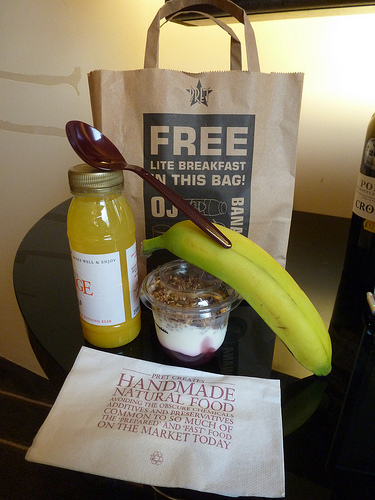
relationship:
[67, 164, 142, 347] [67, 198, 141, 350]
bottle of orange juice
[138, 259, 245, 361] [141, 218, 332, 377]
parfait under banana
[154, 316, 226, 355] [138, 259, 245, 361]
yogurt in parfait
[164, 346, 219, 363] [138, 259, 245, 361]
fruit in parfait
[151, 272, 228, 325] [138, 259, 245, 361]
granola on parfait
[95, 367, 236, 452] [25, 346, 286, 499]
print on napkin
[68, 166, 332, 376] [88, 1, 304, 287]
breakfast next to bag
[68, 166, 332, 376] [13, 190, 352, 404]
breakfast on table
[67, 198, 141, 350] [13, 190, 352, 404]
orange juice on table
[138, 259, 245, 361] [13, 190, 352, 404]
parfait on table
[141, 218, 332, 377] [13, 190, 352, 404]
banana on table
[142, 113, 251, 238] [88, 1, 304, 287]
print on bag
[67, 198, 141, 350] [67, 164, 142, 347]
orange juice in bottle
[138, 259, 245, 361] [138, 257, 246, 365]
parfait in cup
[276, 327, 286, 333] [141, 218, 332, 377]
spot on banana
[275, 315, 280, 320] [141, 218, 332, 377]
spot on banana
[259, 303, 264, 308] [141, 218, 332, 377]
spot on banana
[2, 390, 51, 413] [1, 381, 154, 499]
line on floor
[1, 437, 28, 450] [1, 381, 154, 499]
line on floor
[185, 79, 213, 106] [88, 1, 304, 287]
star on bag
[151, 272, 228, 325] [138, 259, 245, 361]
granola in parfait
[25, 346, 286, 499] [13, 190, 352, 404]
napkin on table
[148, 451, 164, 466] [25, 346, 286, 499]
symbol on napkin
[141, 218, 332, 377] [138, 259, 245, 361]
banana on parfait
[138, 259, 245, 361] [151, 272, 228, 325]
parfait with granola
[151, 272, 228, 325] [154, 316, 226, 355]
granola on yogurt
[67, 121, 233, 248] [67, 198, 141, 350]
spoon on orange juice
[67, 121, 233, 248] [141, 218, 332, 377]
spoon on banana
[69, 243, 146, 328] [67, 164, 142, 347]
label on bottle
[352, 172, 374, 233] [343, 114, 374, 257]
label on bottle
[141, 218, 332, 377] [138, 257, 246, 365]
banana on cup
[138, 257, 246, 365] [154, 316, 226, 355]
cup of yogurt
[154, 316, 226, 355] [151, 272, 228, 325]
yogurt with granola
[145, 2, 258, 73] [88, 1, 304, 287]
handle on bag